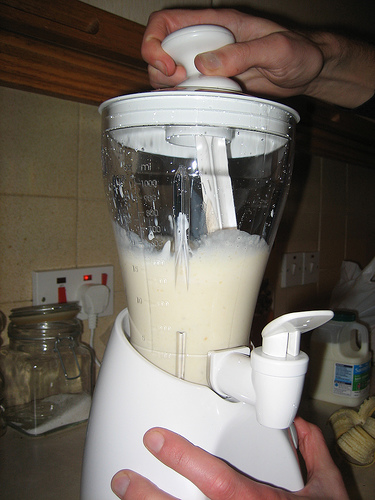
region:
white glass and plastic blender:
[80, 24, 310, 498]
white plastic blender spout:
[207, 302, 335, 436]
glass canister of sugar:
[2, 301, 95, 439]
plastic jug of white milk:
[307, 306, 373, 409]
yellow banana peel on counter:
[327, 397, 374, 466]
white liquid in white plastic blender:
[109, 215, 273, 399]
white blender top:
[151, 24, 243, 97]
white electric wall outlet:
[30, 266, 117, 324]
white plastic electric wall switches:
[284, 255, 324, 288]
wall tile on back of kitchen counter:
[1, 94, 96, 262]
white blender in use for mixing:
[61, 60, 331, 474]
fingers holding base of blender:
[75, 393, 345, 490]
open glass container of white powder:
[1, 286, 93, 441]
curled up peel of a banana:
[315, 377, 368, 462]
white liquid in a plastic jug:
[303, 285, 363, 412]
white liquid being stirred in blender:
[90, 90, 247, 390]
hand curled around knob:
[112, 4, 307, 119]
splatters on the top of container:
[102, 109, 293, 253]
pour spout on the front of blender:
[199, 285, 327, 441]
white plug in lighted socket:
[25, 250, 118, 337]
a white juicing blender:
[74, 18, 333, 497]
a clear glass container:
[4, 301, 97, 436]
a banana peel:
[320, 390, 374, 465]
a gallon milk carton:
[300, 306, 370, 407]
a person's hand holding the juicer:
[105, 407, 351, 494]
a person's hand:
[130, 1, 365, 101]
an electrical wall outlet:
[30, 263, 115, 319]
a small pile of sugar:
[25, 388, 88, 433]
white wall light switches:
[277, 249, 318, 286]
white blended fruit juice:
[118, 245, 259, 377]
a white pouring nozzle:
[203, 299, 345, 441]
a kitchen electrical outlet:
[27, 255, 122, 333]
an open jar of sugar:
[3, 289, 108, 442]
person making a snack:
[13, 4, 368, 482]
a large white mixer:
[65, 99, 346, 495]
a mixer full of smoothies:
[85, 99, 331, 432]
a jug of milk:
[303, 297, 373, 423]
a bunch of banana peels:
[307, 379, 374, 472]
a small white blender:
[54, 47, 340, 494]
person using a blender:
[69, 8, 353, 496]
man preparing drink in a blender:
[61, 7, 342, 497]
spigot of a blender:
[246, 299, 338, 432]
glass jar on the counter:
[2, 295, 101, 442]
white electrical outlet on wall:
[25, 264, 126, 328]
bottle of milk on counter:
[312, 303, 373, 414]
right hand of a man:
[137, 2, 373, 119]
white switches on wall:
[278, 245, 333, 291]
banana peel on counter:
[326, 395, 374, 468]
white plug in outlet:
[74, 281, 118, 315]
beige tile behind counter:
[14, 122, 97, 254]